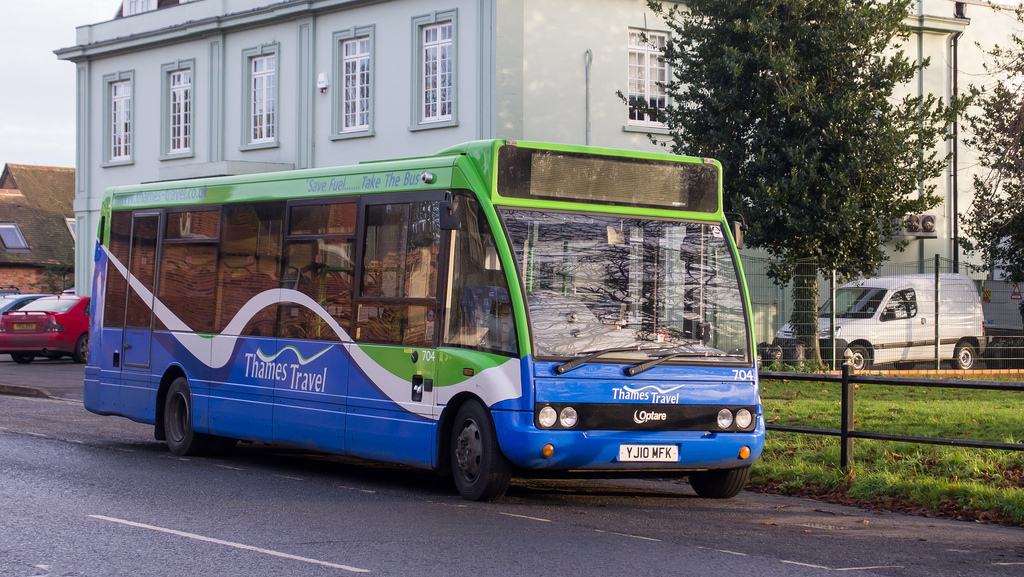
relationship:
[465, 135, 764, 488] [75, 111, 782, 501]
front of bus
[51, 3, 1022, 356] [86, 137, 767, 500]
building behind bus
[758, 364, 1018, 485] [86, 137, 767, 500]
fence near bus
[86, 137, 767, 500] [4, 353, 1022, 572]
bus on street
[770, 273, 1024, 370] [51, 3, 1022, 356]
car next to building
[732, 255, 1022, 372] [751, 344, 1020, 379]
fence along side street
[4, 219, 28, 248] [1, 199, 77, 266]
window in roof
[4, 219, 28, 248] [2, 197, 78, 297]
window on house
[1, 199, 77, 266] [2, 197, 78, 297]
roof on house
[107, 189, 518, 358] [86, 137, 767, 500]
windows on side bus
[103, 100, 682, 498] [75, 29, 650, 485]
wall on building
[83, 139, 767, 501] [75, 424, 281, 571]
bus on street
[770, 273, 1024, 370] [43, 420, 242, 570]
car on street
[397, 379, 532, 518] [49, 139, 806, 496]
tire on bus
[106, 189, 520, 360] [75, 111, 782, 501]
windows on bus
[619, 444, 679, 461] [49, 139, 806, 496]
license plate on bus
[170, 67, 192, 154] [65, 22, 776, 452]
window on building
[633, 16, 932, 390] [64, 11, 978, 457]
tree near building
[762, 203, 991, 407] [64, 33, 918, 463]
car near building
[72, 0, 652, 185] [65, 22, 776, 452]
wall on building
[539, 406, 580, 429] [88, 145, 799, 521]
light on bus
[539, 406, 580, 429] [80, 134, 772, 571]
light on bus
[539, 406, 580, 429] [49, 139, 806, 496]
light on bus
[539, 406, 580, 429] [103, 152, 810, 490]
light on bus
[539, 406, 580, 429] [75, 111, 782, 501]
light on bus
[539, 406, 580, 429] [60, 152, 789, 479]
light on bus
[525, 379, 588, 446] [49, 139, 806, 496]
light on bus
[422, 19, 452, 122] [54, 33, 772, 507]
window on building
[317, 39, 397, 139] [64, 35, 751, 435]
window on building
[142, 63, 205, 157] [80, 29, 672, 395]
window on building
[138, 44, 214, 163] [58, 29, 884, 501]
window on building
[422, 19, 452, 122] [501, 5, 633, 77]
window on building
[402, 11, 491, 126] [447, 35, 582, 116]
window on building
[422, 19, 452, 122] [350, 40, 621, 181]
window on building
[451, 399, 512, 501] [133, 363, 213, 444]
tire with tire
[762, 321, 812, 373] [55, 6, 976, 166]
bags next to building